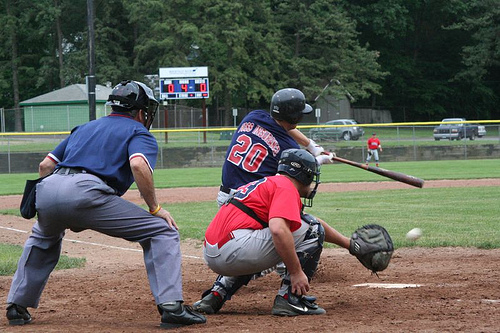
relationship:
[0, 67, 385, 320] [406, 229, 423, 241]
men playing baseball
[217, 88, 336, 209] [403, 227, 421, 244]
batter swinging at ball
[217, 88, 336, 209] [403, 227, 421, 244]
batter missing ball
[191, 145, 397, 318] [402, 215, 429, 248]
catcher catching ball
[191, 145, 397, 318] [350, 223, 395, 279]
catcher wearing catcher's mitt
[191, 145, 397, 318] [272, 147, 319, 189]
catcher wearing helmet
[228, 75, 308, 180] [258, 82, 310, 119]
batter wearing helmet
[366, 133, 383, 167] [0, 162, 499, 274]
man standing in field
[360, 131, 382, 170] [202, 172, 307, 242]
man wearing shirt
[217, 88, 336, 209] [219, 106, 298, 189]
batter wearing blue shirt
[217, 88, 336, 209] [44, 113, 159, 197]
batter wearing blue shirt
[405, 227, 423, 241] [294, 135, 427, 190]
ball going under bat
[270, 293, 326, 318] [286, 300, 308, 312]
shoe with logo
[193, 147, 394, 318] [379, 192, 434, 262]
catcher catching ball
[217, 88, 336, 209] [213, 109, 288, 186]
batter wearing uniform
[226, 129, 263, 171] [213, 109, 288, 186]
20 on uniform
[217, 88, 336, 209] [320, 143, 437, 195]
batter swinging bat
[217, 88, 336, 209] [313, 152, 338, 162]
batter has hand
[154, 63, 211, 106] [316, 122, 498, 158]
scoreboard above fence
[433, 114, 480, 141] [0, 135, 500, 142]
truck on road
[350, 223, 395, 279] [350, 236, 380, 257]
catcher's mitt on hand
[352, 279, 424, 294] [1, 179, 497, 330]
base in dirt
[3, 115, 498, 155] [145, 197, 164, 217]
yellow band on wrist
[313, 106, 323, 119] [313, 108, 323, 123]
sign on pole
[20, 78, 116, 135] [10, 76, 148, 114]
building has roof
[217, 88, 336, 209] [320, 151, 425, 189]
batter swinging baseball bat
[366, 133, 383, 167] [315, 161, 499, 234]
man on baseball field